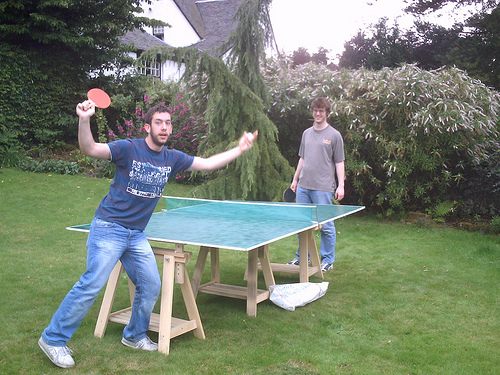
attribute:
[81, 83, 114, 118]
paddle — red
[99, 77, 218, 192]
bush — green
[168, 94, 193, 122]
flowers — pink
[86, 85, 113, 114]
racket — small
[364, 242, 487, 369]
grass — green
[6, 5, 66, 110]
leaves — green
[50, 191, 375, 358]
table — wooden, green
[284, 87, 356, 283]
guy — brown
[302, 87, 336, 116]
hair — curly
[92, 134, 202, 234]
shirt — blue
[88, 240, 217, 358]
saw horse — wooden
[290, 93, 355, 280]
man — brown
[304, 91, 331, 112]
hair — curly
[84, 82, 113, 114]
paddle — red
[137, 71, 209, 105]
flowers — purple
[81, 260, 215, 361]
sawhorse — brown, wooden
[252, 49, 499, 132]
flowers — white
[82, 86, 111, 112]
paddle — red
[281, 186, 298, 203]
paddle — black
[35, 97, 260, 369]
man — blue, light skinned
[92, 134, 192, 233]
shirt — blue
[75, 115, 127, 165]
arm — outstretched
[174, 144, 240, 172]
arm — outstretched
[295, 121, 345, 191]
shirt — gray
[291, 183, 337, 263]
jeans — blue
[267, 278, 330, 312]
bag — white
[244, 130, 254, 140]
ball — white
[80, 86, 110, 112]
racket — red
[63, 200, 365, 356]
table — blue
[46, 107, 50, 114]
leaf — green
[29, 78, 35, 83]
leaf — green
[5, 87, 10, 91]
leaf — green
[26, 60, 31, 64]
leaf — green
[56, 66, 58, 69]
leaf — green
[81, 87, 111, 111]
paddle — pink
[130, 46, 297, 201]
evergreen — sloped over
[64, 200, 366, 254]
table top — green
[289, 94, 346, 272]
man — young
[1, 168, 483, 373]
grass — thick, healthy, green